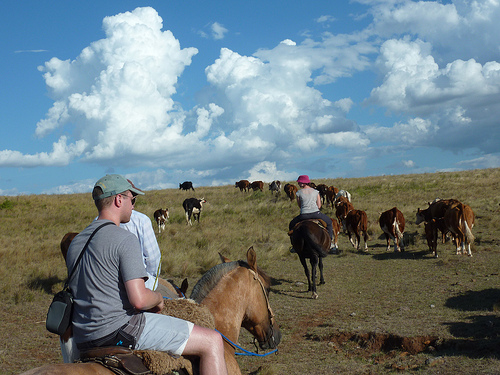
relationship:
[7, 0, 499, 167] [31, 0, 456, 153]
sky has clouds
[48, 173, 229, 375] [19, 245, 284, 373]
man riding a horse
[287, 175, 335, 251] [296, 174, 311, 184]
woman wearing hat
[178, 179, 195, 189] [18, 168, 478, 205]
black cow on hill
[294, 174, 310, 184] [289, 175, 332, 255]
hat on woman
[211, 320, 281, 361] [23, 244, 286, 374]
blue reins on brownhorse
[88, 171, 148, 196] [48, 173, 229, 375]
hat on man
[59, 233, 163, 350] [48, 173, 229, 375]
t shirt on man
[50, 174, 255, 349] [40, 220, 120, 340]
man carrying satchel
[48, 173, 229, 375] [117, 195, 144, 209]
man wearing sunglasses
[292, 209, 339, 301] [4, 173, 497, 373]
cow in field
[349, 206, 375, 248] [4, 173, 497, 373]
cow in field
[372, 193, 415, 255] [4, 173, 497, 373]
cow in field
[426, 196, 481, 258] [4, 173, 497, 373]
cow in field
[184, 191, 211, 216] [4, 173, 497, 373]
cow in field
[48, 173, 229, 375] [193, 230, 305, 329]
man riding horse